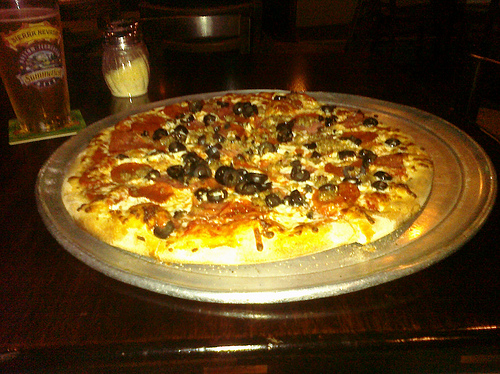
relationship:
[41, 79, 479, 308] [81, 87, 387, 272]
tray under pizza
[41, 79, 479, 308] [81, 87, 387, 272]
tray below pizza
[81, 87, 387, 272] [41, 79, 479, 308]
pizza on tray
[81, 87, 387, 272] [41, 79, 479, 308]
pizza above tray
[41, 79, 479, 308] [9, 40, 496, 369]
tray on table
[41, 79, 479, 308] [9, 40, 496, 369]
tray above table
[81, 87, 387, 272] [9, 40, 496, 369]
pizza on table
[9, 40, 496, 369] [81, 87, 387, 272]
table below pizza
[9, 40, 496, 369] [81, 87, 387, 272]
table under pizza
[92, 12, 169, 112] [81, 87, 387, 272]
jar close to pizza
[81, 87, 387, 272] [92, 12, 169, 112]
pizza close to jar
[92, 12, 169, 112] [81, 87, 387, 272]
jar near pizza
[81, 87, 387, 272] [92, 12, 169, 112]
pizza near jar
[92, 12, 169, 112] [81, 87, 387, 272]
jar beside pizza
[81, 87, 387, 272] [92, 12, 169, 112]
pizza beside jar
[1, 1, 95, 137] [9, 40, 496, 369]
beer on table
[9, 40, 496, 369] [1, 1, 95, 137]
table under beer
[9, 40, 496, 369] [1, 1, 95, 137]
table below beer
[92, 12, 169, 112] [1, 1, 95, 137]
jar beside beer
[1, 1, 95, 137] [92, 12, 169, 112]
beer next to jar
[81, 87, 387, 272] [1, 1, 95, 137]
pizza beside beer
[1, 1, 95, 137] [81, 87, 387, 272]
beer close to pizza